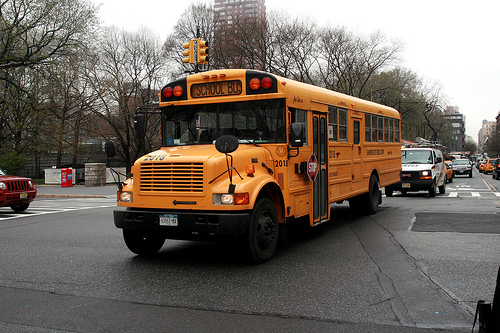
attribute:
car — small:
[383, 143, 446, 194]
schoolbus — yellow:
[102, 68, 402, 265]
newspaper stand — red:
[59, 167, 76, 187]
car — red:
[2, 168, 38, 210]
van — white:
[384, 144, 448, 195]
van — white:
[394, 143, 444, 197]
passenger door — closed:
[310, 109, 334, 227]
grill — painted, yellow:
[136, 161, 210, 198]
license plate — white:
[156, 213, 187, 227]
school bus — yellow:
[108, 65, 406, 263]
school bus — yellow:
[98, 67, 409, 274]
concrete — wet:
[22, 189, 484, 324]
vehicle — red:
[0, 161, 50, 227]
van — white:
[400, 139, 452, 199]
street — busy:
[12, 65, 482, 327]